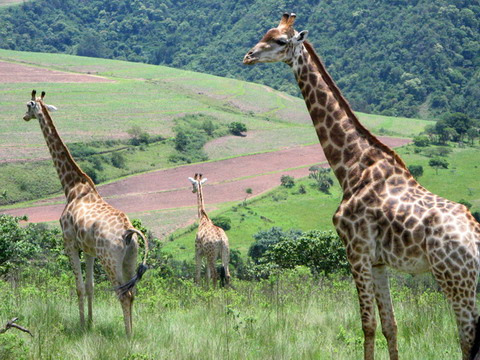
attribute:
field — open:
[7, 0, 478, 357]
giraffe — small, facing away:
[187, 168, 240, 299]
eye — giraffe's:
[267, 32, 298, 48]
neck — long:
[290, 55, 404, 203]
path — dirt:
[15, 146, 333, 228]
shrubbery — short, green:
[3, 212, 346, 306]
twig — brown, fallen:
[3, 311, 44, 345]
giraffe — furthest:
[175, 162, 253, 299]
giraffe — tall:
[18, 83, 181, 344]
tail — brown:
[119, 220, 153, 299]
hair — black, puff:
[118, 263, 155, 300]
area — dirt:
[4, 56, 129, 94]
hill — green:
[3, 47, 435, 182]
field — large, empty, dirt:
[8, 141, 419, 242]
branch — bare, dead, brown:
[5, 309, 46, 350]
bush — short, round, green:
[270, 169, 304, 196]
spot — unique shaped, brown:
[371, 190, 409, 230]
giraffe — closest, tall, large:
[242, 8, 477, 357]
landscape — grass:
[3, 47, 471, 358]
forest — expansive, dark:
[2, 0, 479, 130]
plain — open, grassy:
[2, 51, 479, 236]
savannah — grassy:
[3, 2, 479, 356]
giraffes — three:
[20, 17, 477, 359]